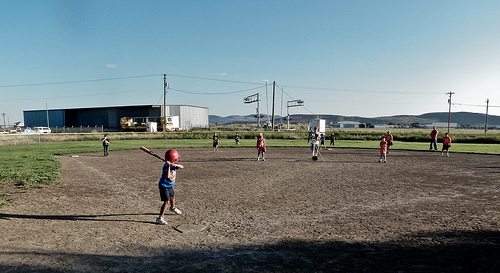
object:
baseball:
[70, 125, 500, 271]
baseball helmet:
[163, 148, 181, 163]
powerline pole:
[162, 73, 168, 125]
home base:
[173, 222, 208, 233]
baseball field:
[0, 146, 500, 273]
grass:
[0, 138, 499, 206]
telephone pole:
[446, 91, 453, 142]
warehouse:
[22, 104, 210, 133]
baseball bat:
[139, 145, 176, 167]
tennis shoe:
[168, 206, 182, 215]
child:
[156, 148, 183, 225]